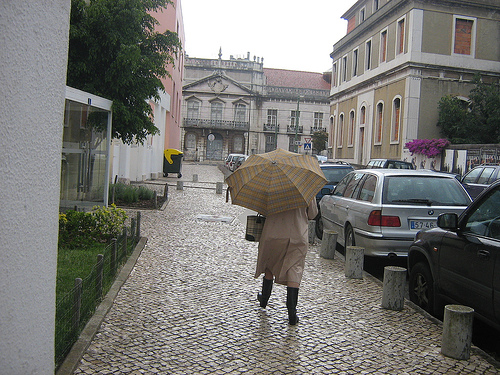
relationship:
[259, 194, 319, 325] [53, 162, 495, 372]
person on sidewalk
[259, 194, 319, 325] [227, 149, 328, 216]
person carrying umbrella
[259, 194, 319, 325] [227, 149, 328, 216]
person has umbrella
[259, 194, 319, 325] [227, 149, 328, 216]
person holding umbrella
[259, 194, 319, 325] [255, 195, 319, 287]
person wearing coat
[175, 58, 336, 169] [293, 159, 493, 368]
building on street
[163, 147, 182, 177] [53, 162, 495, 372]
bin on sidewalk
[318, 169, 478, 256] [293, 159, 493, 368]
car on street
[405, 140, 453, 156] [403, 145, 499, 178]
flowers are on wall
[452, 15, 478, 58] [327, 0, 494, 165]
window on building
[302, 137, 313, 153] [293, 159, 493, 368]
street sign on road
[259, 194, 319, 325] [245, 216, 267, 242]
person holding bag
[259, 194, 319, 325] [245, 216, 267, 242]
person carrying bag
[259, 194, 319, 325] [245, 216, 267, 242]
person has bag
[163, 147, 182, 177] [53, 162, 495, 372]
ash can on sidewalk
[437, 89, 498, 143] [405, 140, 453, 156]
tree has flowers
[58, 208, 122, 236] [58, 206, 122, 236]
bush has flowers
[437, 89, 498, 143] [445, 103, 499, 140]
tree has leaves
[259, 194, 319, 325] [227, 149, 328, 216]
woman holding umbrella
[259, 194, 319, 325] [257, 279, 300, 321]
woman wearing boots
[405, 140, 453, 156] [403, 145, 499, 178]
flowers on wall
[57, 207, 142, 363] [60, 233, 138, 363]
fence near grass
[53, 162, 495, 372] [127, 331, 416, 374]
sidewalk has cobblestones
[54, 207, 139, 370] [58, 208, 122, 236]
garden has plants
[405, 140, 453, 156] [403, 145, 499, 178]
flowers near wall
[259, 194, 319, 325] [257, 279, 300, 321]
person wearing boots